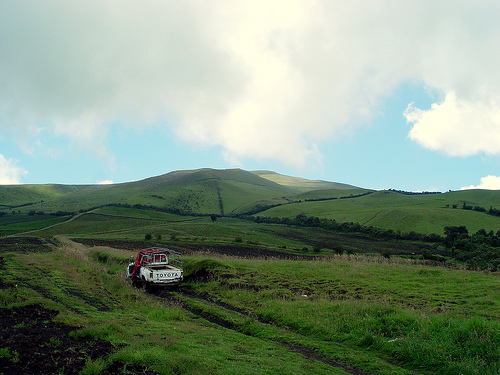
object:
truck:
[126, 248, 185, 293]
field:
[2, 248, 500, 375]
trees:
[440, 225, 471, 240]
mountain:
[122, 168, 371, 223]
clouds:
[405, 88, 500, 161]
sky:
[3, 0, 500, 194]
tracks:
[151, 284, 434, 375]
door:
[133, 253, 143, 278]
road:
[1, 208, 98, 236]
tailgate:
[150, 271, 181, 281]